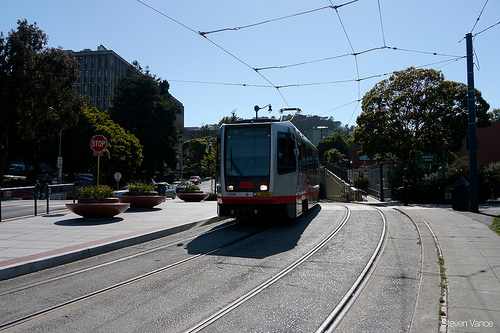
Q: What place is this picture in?
A: It is at the street.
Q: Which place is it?
A: It is a street.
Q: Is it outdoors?
A: Yes, it is outdoors.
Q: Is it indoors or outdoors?
A: It is outdoors.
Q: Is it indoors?
A: No, it is outdoors.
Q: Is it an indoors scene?
A: No, it is outdoors.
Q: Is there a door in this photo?
A: Yes, there is a door.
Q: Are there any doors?
A: Yes, there is a door.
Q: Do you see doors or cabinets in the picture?
A: Yes, there is a door.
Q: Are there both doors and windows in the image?
A: Yes, there are both a door and a window.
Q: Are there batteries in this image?
A: No, there are no batteries.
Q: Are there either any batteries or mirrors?
A: No, there are no batteries or mirrors.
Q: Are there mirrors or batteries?
A: No, there are no batteries or mirrors.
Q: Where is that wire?
A: The wire is in the sky.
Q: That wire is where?
A: The wire is in the sky.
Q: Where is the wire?
A: The wire is in the sky.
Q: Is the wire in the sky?
A: Yes, the wire is in the sky.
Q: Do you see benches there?
A: No, there are no benches.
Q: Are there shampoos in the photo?
A: No, there are no shampoos.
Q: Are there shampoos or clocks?
A: No, there are no shampoos or clocks.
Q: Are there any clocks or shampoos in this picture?
A: No, there are no shampoos or clocks.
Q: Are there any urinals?
A: No, there are no urinals.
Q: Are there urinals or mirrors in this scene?
A: No, there are no urinals or mirrors.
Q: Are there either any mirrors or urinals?
A: No, there are no urinals or mirrors.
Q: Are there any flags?
A: No, there are no flags.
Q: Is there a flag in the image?
A: No, there are no flags.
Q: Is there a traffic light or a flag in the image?
A: No, there are no flags or traffic lights.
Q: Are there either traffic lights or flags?
A: No, there are no flags or traffic lights.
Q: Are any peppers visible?
A: No, there are no peppers.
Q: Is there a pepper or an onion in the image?
A: No, there are no peppers or onions.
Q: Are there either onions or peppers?
A: No, there are no peppers or onions.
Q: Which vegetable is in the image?
A: The vegetable is cauliflower.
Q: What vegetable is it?
A: The vegetable is cauliflower.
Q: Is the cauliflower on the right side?
A: Yes, the cauliflower is on the right of the image.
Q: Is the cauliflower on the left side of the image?
A: No, the cauliflower is on the right of the image.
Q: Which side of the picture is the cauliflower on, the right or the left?
A: The cauliflower is on the right of the image.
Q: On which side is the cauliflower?
A: The cauliflower is on the right of the image.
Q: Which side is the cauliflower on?
A: The cauliflower is on the right of the image.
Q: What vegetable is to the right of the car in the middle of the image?
A: The vegetable is cauliflower.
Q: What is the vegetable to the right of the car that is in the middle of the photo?
A: The vegetable is cauliflower.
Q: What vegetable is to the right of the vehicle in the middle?
A: The vegetable is cauliflower.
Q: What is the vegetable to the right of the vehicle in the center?
A: The vegetable is cauliflower.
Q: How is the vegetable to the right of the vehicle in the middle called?
A: The vegetable is cauliflower.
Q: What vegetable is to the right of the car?
A: The vegetable is cauliflower.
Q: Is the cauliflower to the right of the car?
A: Yes, the cauliflower is to the right of the car.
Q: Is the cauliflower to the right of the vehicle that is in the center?
A: Yes, the cauliflower is to the right of the car.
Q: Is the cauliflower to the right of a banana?
A: No, the cauliflower is to the right of the car.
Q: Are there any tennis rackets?
A: No, there are no tennis rackets.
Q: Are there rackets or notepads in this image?
A: No, there are no rackets or notepads.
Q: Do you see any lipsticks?
A: No, there are no lipsticks.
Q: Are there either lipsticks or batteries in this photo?
A: No, there are no lipsticks or batteries.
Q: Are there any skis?
A: No, there are no skis.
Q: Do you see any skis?
A: No, there are no skis.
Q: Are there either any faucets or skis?
A: No, there are no skis or faucets.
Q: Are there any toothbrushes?
A: No, there are no toothbrushes.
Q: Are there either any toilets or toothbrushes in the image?
A: No, there are no toothbrushes or toilets.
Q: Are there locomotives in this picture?
A: No, there are no locomotives.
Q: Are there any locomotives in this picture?
A: No, there are no locomotives.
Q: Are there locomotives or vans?
A: No, there are no locomotives or vans.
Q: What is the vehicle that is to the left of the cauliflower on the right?
A: The vehicle is a car.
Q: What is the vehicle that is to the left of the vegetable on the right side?
A: The vehicle is a car.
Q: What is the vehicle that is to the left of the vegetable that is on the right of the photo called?
A: The vehicle is a car.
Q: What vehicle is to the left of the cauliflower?
A: The vehicle is a car.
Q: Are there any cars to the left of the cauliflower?
A: Yes, there is a car to the left of the cauliflower.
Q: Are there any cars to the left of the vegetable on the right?
A: Yes, there is a car to the left of the cauliflower.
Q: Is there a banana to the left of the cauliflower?
A: No, there is a car to the left of the cauliflower.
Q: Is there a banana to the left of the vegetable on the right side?
A: No, there is a car to the left of the cauliflower.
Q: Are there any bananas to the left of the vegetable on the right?
A: No, there is a car to the left of the cauliflower.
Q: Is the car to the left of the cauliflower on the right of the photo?
A: Yes, the car is to the left of the cauliflower.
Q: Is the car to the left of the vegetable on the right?
A: Yes, the car is to the left of the cauliflower.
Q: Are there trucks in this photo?
A: No, there are no trucks.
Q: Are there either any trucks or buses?
A: No, there are no trucks or buses.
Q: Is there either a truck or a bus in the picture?
A: No, there are no trucks or buses.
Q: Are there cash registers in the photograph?
A: No, there are no cash registers.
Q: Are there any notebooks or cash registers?
A: No, there are no cash registers or notebooks.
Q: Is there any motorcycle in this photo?
A: No, there are no motorcycles.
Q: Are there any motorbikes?
A: No, there are no motorbikes.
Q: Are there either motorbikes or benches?
A: No, there are no motorbikes or benches.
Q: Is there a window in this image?
A: Yes, there is a window.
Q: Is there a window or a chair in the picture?
A: Yes, there is a window.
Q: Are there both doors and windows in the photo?
A: Yes, there are both a window and a door.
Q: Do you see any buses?
A: No, there are no buses.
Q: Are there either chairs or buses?
A: No, there are no buses or chairs.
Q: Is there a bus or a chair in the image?
A: No, there are no buses or chairs.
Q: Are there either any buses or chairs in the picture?
A: No, there are no buses or chairs.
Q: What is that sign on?
A: The sign is on the pole.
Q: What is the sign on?
A: The sign is on the pole.